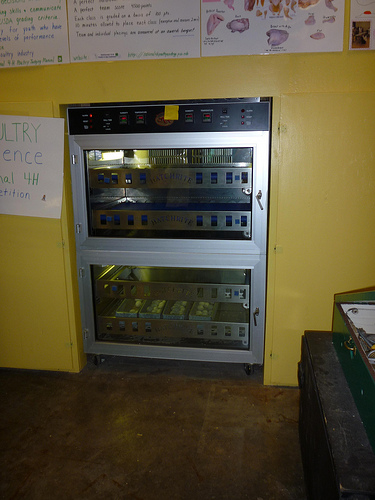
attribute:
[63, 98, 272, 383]
oven — double stacked, commercial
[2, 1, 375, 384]
wall — yellow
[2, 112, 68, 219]
sign — handwritten, white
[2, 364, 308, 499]
floor — concrete, dark, dirty, brown, old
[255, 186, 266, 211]
handle — silver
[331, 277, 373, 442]
box — green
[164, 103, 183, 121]
sticky note — yellow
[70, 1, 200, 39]
writing — black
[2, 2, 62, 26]
writing — green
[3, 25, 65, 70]
writing — blue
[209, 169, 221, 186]
object — blue